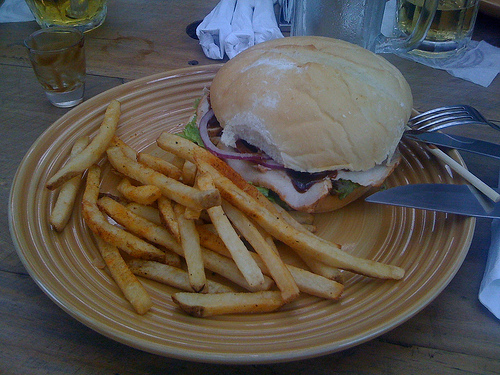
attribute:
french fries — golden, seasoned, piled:
[45, 99, 405, 315]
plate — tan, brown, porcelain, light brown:
[8, 64, 476, 364]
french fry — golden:
[47, 100, 121, 191]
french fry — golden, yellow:
[49, 136, 89, 231]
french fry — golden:
[172, 289, 286, 317]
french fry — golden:
[191, 154, 404, 282]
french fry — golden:
[106, 146, 222, 210]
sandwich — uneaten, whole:
[175, 35, 414, 214]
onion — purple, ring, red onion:
[200, 108, 285, 170]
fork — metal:
[407, 105, 499, 133]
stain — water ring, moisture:
[99, 35, 162, 63]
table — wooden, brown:
[1, 1, 500, 374]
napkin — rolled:
[195, 0, 237, 61]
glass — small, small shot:
[25, 26, 86, 110]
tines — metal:
[408, 104, 474, 132]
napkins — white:
[0, 0, 499, 320]